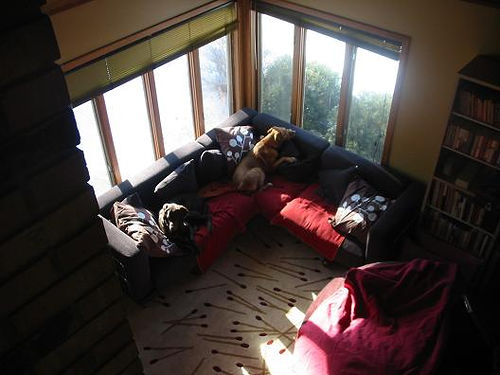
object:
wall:
[49, 3, 132, 44]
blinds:
[246, 0, 414, 165]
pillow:
[213, 125, 263, 167]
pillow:
[151, 158, 210, 206]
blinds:
[67, 35, 238, 203]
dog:
[155, 189, 216, 256]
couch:
[84, 104, 420, 292]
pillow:
[332, 178, 397, 238]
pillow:
[110, 191, 173, 254]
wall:
[405, 9, 467, 36]